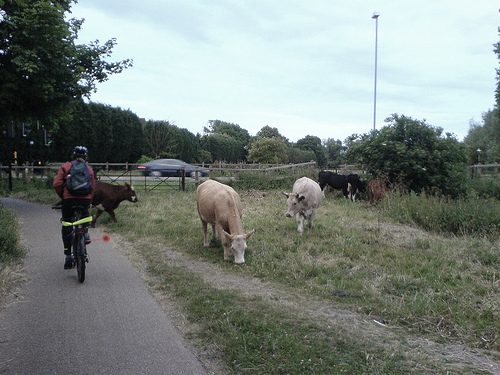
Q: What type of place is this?
A: It is a path.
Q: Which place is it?
A: It is a path.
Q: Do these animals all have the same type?
A: Yes, all the animals are cows.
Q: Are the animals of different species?
A: No, all the animals are cows.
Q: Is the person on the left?
A: Yes, the person is on the left of the image.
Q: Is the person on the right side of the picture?
A: No, the person is on the left of the image.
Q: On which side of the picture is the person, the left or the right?
A: The person is on the left of the image.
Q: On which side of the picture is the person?
A: The person is on the left of the image.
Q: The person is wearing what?
A: The person is wearing a jacket.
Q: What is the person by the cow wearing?
A: The person is wearing a jacket.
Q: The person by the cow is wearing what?
A: The person is wearing a jacket.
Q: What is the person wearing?
A: The person is wearing a jacket.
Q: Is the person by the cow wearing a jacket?
A: Yes, the person is wearing a jacket.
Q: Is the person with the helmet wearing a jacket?
A: Yes, the person is wearing a jacket.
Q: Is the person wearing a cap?
A: No, the person is wearing a jacket.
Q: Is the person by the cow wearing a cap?
A: No, the person is wearing a jacket.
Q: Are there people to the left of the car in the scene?
A: Yes, there is a person to the left of the car.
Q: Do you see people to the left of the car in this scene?
A: Yes, there is a person to the left of the car.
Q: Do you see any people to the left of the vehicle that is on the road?
A: Yes, there is a person to the left of the car.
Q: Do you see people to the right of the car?
A: No, the person is to the left of the car.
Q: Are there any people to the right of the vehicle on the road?
A: No, the person is to the left of the car.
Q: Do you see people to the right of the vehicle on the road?
A: No, the person is to the left of the car.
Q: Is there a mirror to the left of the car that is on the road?
A: No, there is a person to the left of the car.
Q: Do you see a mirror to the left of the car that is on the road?
A: No, there is a person to the left of the car.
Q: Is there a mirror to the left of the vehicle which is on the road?
A: No, there is a person to the left of the car.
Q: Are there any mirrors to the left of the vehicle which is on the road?
A: No, there is a person to the left of the car.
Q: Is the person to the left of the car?
A: Yes, the person is to the left of the car.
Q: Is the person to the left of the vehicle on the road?
A: Yes, the person is to the left of the car.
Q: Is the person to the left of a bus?
A: No, the person is to the left of the car.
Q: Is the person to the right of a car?
A: No, the person is to the left of a car.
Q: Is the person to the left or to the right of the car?
A: The person is to the left of the car.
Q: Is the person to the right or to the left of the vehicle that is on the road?
A: The person is to the left of the car.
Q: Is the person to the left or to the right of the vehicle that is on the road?
A: The person is to the left of the car.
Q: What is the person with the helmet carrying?
A: The person is carrying a backpack.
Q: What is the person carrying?
A: The person is carrying a backpack.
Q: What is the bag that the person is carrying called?
A: The bag is a backpack.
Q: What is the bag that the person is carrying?
A: The bag is a backpack.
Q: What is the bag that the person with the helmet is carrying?
A: The bag is a backpack.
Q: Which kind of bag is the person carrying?
A: The person is carrying a backpack.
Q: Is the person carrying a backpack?
A: Yes, the person is carrying a backpack.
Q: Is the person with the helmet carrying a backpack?
A: Yes, the person is carrying a backpack.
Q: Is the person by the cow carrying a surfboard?
A: No, the person is carrying a backpack.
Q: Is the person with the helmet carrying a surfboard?
A: No, the person is carrying a backpack.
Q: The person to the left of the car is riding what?
A: The person is riding a bike.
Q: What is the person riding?
A: The person is riding a bike.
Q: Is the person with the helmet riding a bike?
A: Yes, the person is riding a bike.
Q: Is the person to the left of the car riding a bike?
A: Yes, the person is riding a bike.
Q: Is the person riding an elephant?
A: No, the person is riding a bike.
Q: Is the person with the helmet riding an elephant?
A: No, the person is riding a bike.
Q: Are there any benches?
A: No, there are no benches.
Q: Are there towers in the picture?
A: No, there are no towers.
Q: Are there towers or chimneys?
A: No, there are no towers or chimneys.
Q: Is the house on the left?
A: Yes, the house is on the left of the image.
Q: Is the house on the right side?
A: No, the house is on the left of the image.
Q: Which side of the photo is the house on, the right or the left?
A: The house is on the left of the image.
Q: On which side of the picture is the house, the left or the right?
A: The house is on the left of the image.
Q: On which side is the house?
A: The house is on the left of the image.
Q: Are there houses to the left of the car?
A: Yes, there is a house to the left of the car.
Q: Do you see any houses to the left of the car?
A: Yes, there is a house to the left of the car.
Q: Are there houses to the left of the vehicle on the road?
A: Yes, there is a house to the left of the car.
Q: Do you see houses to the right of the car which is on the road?
A: No, the house is to the left of the car.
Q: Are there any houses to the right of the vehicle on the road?
A: No, the house is to the left of the car.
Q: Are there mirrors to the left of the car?
A: No, there is a house to the left of the car.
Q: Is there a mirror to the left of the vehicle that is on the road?
A: No, there is a house to the left of the car.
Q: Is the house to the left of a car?
A: Yes, the house is to the left of a car.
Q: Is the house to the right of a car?
A: No, the house is to the left of a car.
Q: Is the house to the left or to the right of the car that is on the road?
A: The house is to the left of the car.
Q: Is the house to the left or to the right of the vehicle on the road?
A: The house is to the left of the car.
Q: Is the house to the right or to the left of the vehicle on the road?
A: The house is to the left of the car.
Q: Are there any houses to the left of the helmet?
A: Yes, there is a house to the left of the helmet.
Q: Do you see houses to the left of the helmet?
A: Yes, there is a house to the left of the helmet.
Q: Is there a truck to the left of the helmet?
A: No, there is a house to the left of the helmet.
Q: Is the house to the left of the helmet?
A: Yes, the house is to the left of the helmet.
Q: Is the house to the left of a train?
A: No, the house is to the left of the helmet.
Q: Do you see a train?
A: No, there are no trains.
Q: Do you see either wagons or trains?
A: No, there are no trains or wagons.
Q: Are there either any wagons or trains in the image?
A: No, there are no trains or wagons.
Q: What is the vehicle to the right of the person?
A: The vehicle is a car.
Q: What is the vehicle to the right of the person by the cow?
A: The vehicle is a car.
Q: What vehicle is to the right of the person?
A: The vehicle is a car.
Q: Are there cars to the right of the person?
A: Yes, there is a car to the right of the person.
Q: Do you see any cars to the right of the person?
A: Yes, there is a car to the right of the person.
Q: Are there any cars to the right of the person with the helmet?
A: Yes, there is a car to the right of the person.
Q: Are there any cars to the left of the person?
A: No, the car is to the right of the person.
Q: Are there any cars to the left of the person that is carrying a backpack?
A: No, the car is to the right of the person.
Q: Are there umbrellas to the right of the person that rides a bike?
A: No, there is a car to the right of the person.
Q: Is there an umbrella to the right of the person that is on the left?
A: No, there is a car to the right of the person.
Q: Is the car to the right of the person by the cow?
A: Yes, the car is to the right of the person.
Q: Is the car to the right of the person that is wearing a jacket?
A: Yes, the car is to the right of the person.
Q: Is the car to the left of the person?
A: No, the car is to the right of the person.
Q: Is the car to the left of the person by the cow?
A: No, the car is to the right of the person.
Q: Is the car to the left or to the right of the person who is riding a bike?
A: The car is to the right of the person.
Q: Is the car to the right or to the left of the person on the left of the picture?
A: The car is to the right of the person.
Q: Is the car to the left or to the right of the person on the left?
A: The car is to the right of the person.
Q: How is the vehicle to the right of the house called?
A: The vehicle is a car.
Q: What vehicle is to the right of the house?
A: The vehicle is a car.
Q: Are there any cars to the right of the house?
A: Yes, there is a car to the right of the house.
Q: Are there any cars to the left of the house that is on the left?
A: No, the car is to the right of the house.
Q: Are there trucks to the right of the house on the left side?
A: No, there is a car to the right of the house.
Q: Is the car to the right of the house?
A: Yes, the car is to the right of the house.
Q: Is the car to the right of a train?
A: No, the car is to the right of the house.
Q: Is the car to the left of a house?
A: No, the car is to the right of a house.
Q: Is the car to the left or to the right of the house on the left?
A: The car is to the right of the house.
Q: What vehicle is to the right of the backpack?
A: The vehicle is a car.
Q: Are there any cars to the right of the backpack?
A: Yes, there is a car to the right of the backpack.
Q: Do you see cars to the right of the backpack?
A: Yes, there is a car to the right of the backpack.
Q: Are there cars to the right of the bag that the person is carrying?
A: Yes, there is a car to the right of the backpack.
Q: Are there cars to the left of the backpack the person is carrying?
A: No, the car is to the right of the backpack.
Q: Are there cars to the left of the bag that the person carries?
A: No, the car is to the right of the backpack.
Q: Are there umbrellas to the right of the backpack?
A: No, there is a car to the right of the backpack.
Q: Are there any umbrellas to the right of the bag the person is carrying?
A: No, there is a car to the right of the backpack.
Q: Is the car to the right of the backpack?
A: Yes, the car is to the right of the backpack.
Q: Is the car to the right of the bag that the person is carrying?
A: Yes, the car is to the right of the backpack.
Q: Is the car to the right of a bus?
A: No, the car is to the right of the backpack.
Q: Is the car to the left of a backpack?
A: No, the car is to the right of a backpack.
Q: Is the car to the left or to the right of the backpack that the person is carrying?
A: The car is to the right of the backpack.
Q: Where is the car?
A: The car is on the road.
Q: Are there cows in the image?
A: Yes, there is a cow.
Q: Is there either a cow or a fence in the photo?
A: Yes, there is a cow.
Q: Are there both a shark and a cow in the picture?
A: No, there is a cow but no sharks.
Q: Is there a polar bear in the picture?
A: No, there are no polar bears.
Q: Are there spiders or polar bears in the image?
A: No, there are no polar bears or spiders.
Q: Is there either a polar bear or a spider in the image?
A: No, there are no polar bears or spiders.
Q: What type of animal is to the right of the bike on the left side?
A: The animal is a cow.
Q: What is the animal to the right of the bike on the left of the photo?
A: The animal is a cow.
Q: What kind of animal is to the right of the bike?
A: The animal is a cow.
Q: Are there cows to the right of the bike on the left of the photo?
A: Yes, there is a cow to the right of the bike.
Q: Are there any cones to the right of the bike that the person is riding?
A: No, there is a cow to the right of the bike.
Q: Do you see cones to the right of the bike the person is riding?
A: No, there is a cow to the right of the bike.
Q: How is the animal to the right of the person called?
A: The animal is a cow.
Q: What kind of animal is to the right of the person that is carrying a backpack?
A: The animal is a cow.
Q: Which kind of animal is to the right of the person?
A: The animal is a cow.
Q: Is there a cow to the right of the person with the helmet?
A: Yes, there is a cow to the right of the person.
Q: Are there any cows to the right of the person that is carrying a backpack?
A: Yes, there is a cow to the right of the person.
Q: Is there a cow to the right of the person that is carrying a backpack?
A: Yes, there is a cow to the right of the person.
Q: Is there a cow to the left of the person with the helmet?
A: No, the cow is to the right of the person.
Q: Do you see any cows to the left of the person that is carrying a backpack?
A: No, the cow is to the right of the person.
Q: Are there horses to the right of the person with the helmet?
A: No, there is a cow to the right of the person.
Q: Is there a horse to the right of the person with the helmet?
A: No, there is a cow to the right of the person.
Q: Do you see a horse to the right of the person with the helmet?
A: No, there is a cow to the right of the person.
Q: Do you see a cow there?
A: Yes, there is a cow.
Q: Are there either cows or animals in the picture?
A: Yes, there is a cow.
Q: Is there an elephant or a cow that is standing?
A: Yes, the cow is standing.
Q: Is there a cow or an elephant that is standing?
A: Yes, the cow is standing.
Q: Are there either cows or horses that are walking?
A: Yes, the cow is walking.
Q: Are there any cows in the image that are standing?
A: Yes, there is a cow that is standing.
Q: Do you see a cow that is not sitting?
A: Yes, there is a cow that is standing .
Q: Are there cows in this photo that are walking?
A: Yes, there is a cow that is walking.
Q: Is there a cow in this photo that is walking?
A: Yes, there is a cow that is walking.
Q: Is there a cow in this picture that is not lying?
A: Yes, there is a cow that is walking.